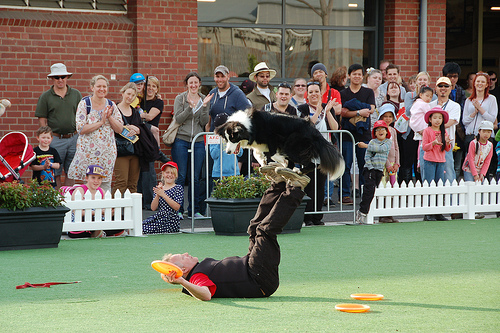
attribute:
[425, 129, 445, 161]
tshirt — PINK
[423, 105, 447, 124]
hat — red 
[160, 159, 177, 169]
hat — red 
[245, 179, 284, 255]
leg — up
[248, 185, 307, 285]
leg — up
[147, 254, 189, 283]
frisbee — yellow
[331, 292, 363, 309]
frisbee — yellow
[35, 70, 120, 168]
man — green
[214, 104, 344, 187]
dog — black